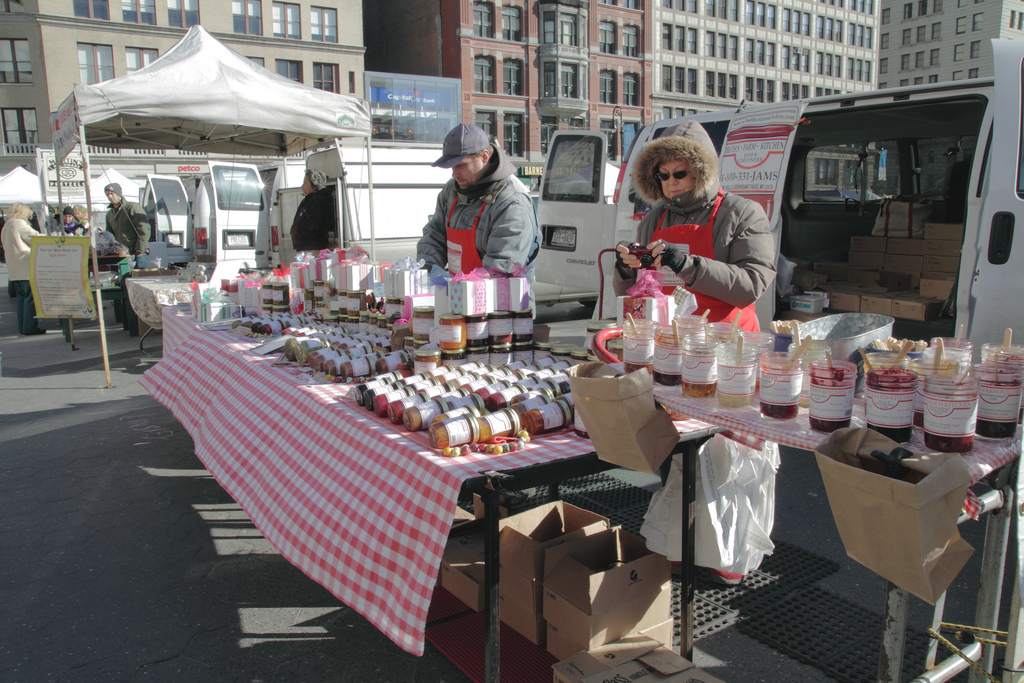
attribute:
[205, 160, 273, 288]
door — open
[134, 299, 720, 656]
tablecloth — red, checkered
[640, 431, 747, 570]
bag — hanging, plastic, white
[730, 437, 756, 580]
bag — hanging, plastic, white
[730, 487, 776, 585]
bag — hanging, plastic, white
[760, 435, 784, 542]
bag — hanging, plastic, white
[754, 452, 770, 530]
bag — hanging, plastic, white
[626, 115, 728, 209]
hood — fur-lined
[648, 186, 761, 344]
apron — red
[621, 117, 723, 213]
hood — furry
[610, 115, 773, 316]
jacket — grey in color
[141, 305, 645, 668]
table cloth — checkered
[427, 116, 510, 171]
cap — grey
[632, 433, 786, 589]
shopping bags — plastic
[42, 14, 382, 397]
tent — large, white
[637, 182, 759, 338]
apron — red